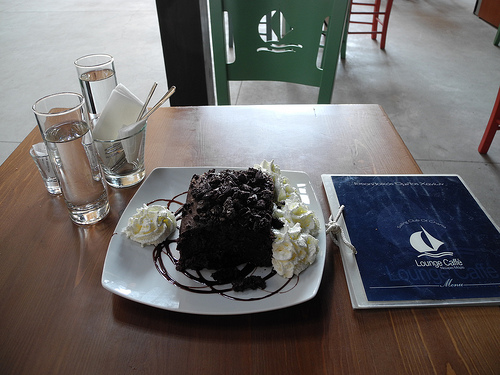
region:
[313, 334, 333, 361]
THE TABLE IS WOODEN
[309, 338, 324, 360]
THE TABLE IS WOODEN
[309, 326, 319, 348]
THE TABLE IS WOODEN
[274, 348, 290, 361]
THE TABLE IS WOODEN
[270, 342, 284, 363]
THE TABLE IS WOODEN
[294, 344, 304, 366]
THE TABLE IS WOODEN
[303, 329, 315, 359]
THE TABLE IS WOODEN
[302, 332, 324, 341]
THE TABLE IS WOODEN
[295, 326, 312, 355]
THE TABLE IS WOODEN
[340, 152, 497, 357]
the menu is blue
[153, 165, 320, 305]
a chocolate cake on a white plate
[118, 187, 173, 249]
whipped cream on a white plate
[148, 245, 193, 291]
chocolate sauce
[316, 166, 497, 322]
a restaurant menu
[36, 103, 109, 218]
a glass of water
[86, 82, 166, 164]
a glass with a white napkin and utensils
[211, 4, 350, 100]
the green seat of a chair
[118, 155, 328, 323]
a chocolate cake with whipped cream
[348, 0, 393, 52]
the legs of a red chair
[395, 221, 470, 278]
the logo of a boat on a menu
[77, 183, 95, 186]
the glass is clear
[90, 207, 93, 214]
the glass is clear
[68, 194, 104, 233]
the glass is clear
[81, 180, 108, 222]
the glass is clear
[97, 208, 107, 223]
the glass is clear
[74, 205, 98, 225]
the glass is clear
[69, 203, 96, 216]
the glass is clear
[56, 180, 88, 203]
the glass is clear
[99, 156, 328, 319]
chocolate cake with cream all on a white plate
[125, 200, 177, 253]
whipped cream on a plate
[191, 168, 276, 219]
chocolate shavings on a piece of chocolate cake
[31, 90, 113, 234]
tall glass of water on a wooden table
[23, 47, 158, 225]
glasses on a wooden table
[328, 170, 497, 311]
blue lounge cafe menu on a wooden table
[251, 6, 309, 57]
saliboat design on a green chair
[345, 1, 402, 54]
bottom of a red chair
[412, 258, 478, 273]
white print on a menu reading Lounge Cafe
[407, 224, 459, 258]
sailboat logo design on a blue menu